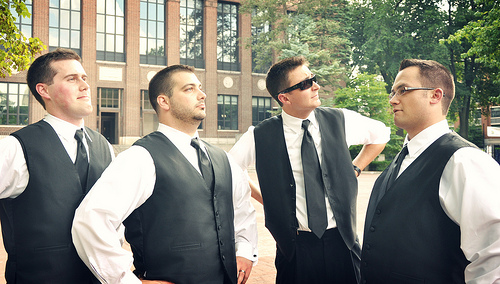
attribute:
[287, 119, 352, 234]
tie — black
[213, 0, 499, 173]
trees — Green 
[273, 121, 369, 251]
vest — open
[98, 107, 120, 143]
door — entrance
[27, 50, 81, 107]
hair — brown 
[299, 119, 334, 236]
tie — black 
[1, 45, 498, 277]
men — four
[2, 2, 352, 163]
building — large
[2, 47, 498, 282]
people — four, standing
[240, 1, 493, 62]
trees — green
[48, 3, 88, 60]
window — closed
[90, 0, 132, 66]
window — closed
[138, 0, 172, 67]
window — closed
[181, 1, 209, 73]
window — closed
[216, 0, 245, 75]
window — closed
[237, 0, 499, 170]
leaves — green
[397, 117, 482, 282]
shirt — white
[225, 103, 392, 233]
shirt — white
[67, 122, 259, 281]
shirt — white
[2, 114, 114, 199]
shirt — white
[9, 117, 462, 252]
vests — blacks